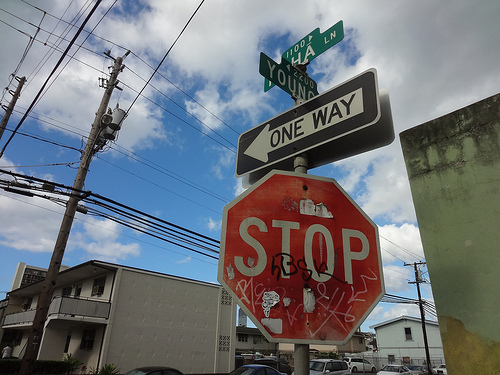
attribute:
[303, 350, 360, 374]
van — white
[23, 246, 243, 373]
building — gray, dilapidated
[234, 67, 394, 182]
sign — black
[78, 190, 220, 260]
wires — black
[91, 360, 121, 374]
bush — small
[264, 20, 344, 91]
sign — green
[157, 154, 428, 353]
sign — white, black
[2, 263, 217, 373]
building — white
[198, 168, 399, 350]
sign — red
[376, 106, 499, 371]
stucture — large, concrete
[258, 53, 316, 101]
street sign — green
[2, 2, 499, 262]
sky — cloudy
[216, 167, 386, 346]
sign — red, white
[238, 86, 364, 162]
arrow — white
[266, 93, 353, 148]
writing — black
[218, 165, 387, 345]
stop sign — red, white